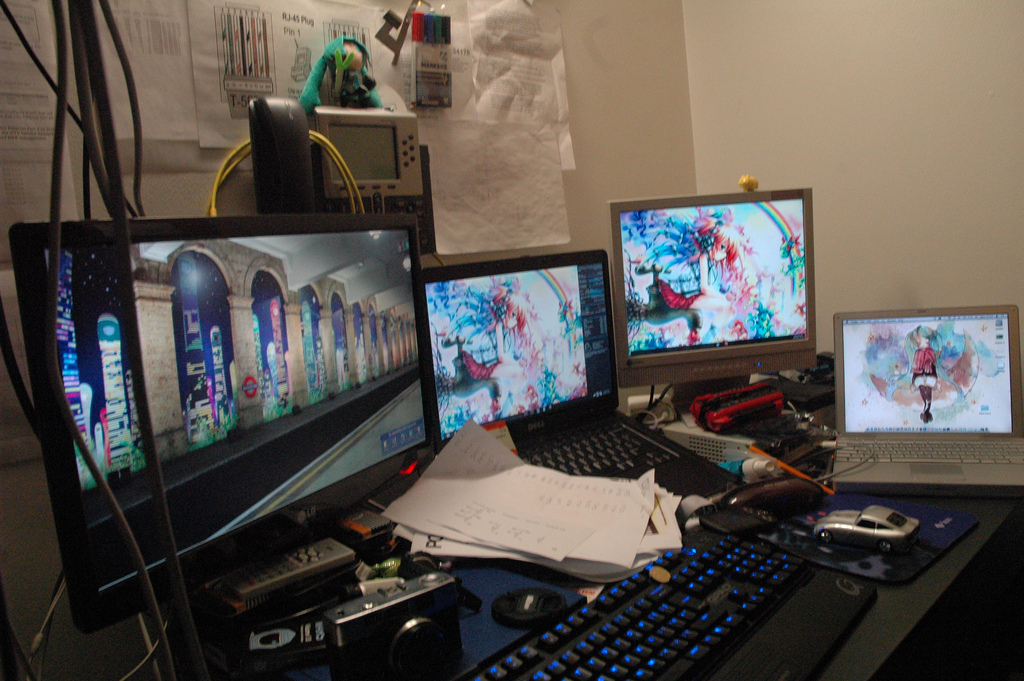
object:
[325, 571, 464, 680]
camera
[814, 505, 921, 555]
toy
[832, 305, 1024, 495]
laptop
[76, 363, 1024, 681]
desk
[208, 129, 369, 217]
cord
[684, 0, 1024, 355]
wall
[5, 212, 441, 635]
monitor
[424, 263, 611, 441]
screen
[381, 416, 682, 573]
papers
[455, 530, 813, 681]
keyboard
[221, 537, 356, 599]
remote control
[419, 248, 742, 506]
laptop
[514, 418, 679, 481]
keyboard